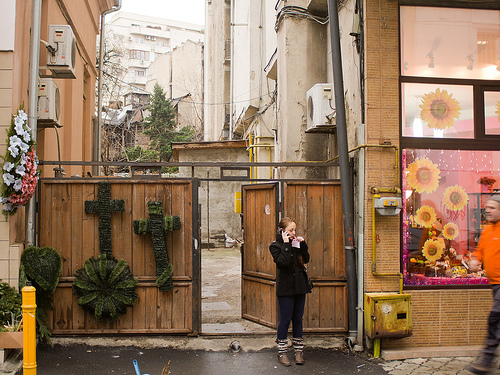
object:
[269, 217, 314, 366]
woman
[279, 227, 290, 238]
cell phone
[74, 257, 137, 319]
wreath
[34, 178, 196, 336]
wall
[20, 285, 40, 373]
pole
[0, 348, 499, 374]
street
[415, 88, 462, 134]
sunflower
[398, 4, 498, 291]
window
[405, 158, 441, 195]
sunflower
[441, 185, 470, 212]
sunflower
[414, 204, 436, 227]
sunflower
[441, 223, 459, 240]
sunflower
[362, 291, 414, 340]
gas meter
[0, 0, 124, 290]
wall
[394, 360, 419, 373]
brick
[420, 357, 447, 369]
brick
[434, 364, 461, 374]
brick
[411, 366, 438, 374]
brick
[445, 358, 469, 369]
brick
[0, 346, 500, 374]
pavement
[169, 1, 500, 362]
building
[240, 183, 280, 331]
gate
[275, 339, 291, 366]
boots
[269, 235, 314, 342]
clothes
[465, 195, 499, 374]
man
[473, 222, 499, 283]
sweatshirt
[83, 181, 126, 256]
cross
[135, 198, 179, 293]
cross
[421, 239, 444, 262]
sunflower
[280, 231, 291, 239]
hand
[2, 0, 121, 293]
building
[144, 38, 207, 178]
building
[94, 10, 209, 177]
building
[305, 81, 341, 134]
fan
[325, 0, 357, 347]
pipe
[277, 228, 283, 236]
ear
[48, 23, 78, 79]
air conditioner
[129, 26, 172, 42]
balcony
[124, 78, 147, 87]
balcony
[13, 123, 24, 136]
flower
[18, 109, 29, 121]
flower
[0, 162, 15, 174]
flower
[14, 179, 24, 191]
flower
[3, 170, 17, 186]
flower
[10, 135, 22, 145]
flower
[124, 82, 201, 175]
tree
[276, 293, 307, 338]
pants